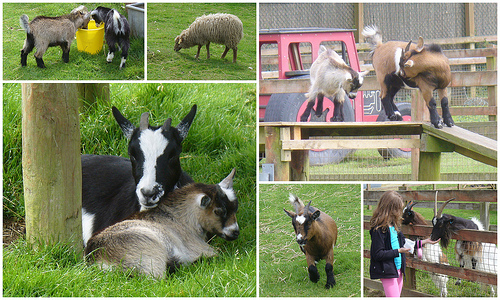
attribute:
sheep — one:
[174, 11, 241, 62]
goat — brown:
[353, 23, 463, 131]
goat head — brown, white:
[280, 204, 325, 246]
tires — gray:
[271, 72, 434, 178]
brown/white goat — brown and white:
[112, 180, 241, 287]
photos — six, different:
[38, 16, 465, 246]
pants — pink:
[386, 266, 406, 299]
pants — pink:
[379, 270, 403, 299]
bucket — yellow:
[72, 15, 109, 60]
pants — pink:
[382, 267, 405, 294]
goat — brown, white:
[277, 187, 342, 284]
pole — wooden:
[8, 99, 103, 226]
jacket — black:
[368, 221, 409, 283]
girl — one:
[370, 192, 415, 299]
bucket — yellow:
[69, 16, 127, 70]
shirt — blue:
[384, 227, 403, 271]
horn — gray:
[134, 108, 156, 132]